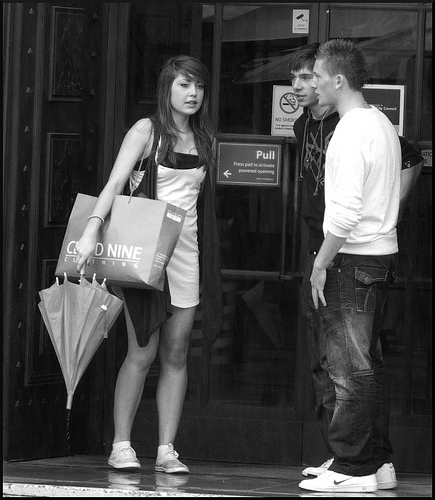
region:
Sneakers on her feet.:
[106, 442, 193, 476]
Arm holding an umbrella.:
[38, 223, 115, 418]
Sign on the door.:
[211, 141, 293, 195]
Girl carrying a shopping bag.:
[38, 120, 168, 289]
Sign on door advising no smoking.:
[265, 79, 309, 145]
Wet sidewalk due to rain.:
[15, 468, 295, 492]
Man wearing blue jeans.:
[290, 245, 404, 481]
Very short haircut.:
[301, 39, 374, 110]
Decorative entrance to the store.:
[14, 8, 103, 107]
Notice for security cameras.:
[266, 6, 328, 40]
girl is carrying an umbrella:
[41, 249, 118, 409]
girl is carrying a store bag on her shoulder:
[66, 169, 193, 308]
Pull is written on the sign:
[254, 144, 276, 161]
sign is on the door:
[208, 131, 286, 200]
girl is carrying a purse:
[123, 153, 180, 354]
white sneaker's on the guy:
[297, 454, 414, 497]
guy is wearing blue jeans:
[298, 236, 412, 472]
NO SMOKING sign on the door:
[264, 78, 320, 148]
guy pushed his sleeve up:
[310, 201, 384, 301]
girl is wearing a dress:
[118, 110, 210, 319]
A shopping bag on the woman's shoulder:
[58, 113, 215, 291]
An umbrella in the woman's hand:
[32, 218, 143, 415]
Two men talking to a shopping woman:
[72, 69, 403, 442]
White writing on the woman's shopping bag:
[58, 231, 148, 270]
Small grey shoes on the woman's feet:
[103, 435, 193, 474]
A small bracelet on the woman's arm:
[86, 212, 111, 228]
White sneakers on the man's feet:
[311, 461, 402, 497]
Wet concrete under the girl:
[50, 471, 195, 493]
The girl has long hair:
[147, 63, 244, 172]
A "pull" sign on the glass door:
[212, 135, 282, 189]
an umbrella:
[24, 248, 125, 415]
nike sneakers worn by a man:
[300, 445, 402, 492]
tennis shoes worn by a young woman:
[104, 434, 191, 478]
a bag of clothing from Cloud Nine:
[44, 179, 204, 299]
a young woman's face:
[156, 53, 216, 128]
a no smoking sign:
[272, 85, 303, 135]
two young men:
[284, 38, 365, 117]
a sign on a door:
[213, 139, 281, 190]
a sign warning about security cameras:
[288, 8, 315, 42]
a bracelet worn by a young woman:
[82, 208, 115, 233]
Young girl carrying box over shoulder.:
[55, 113, 195, 292]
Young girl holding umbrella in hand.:
[40, 240, 130, 414]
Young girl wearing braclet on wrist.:
[83, 210, 115, 229]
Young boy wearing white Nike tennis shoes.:
[296, 455, 399, 499]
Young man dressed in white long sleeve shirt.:
[316, 104, 413, 258]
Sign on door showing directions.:
[215, 138, 282, 193]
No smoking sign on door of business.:
[266, 82, 310, 150]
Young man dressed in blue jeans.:
[314, 248, 402, 475]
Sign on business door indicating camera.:
[287, 5, 315, 36]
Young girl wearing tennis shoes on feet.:
[106, 443, 193, 480]